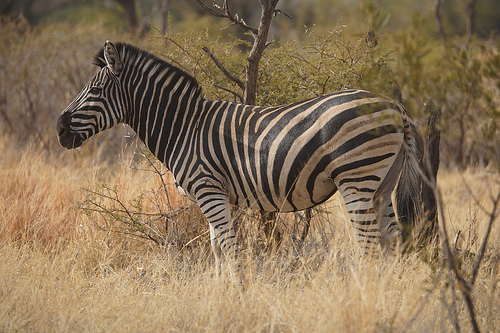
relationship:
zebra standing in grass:
[52, 30, 452, 317] [114, 213, 386, 329]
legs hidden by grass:
[292, 173, 446, 316] [167, 220, 419, 329]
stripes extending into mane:
[136, 55, 212, 156] [123, 53, 201, 103]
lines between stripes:
[330, 113, 386, 153] [312, 99, 393, 219]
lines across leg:
[192, 184, 226, 231] [183, 184, 250, 274]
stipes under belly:
[243, 162, 317, 229] [216, 153, 354, 234]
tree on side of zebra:
[281, 2, 475, 134] [52, 50, 432, 310]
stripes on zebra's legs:
[196, 170, 236, 222] [168, 170, 264, 280]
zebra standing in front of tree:
[52, 30, 452, 317] [205, 4, 301, 118]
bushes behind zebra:
[228, 28, 464, 128] [52, 30, 452, 317]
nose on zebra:
[50, 104, 77, 135] [51, 35, 447, 258]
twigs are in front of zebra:
[403, 141, 498, 327] [51, 35, 447, 258]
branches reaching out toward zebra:
[89, 165, 189, 257] [51, 35, 447, 258]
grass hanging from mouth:
[58, 136, 84, 180] [53, 107, 90, 152]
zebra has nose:
[52, 30, 452, 317] [43, 114, 81, 160]